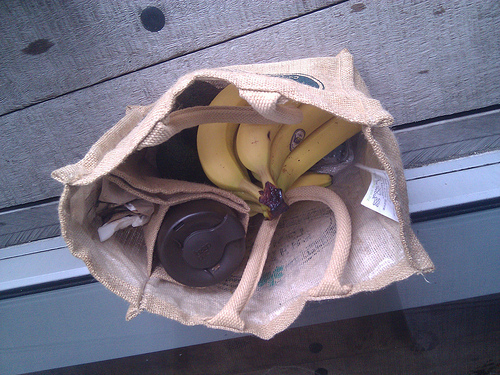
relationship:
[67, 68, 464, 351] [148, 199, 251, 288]
bag has mug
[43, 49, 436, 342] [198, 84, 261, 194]
bag has banana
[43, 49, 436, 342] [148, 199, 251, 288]
bag has mug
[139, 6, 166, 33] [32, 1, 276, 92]
marks on wood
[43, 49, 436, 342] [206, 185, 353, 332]
bag with handle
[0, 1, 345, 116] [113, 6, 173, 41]
board with marks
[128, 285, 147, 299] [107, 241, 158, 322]
stiches on seam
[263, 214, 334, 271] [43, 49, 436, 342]
ink on bag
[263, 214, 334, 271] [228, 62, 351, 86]
ink on back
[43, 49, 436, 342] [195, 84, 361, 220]
bag of fruit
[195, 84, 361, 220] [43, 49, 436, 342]
fruit in bag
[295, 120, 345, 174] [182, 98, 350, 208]
banana in bunch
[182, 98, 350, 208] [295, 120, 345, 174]
bunch of banana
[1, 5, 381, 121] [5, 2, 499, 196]
crack on floor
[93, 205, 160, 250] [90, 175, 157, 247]
material in bag